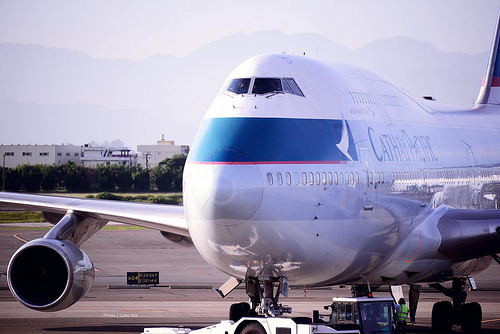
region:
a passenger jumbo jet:
[23, 31, 490, 323]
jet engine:
[6, 227, 97, 313]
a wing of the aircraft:
[5, 171, 190, 243]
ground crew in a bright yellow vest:
[388, 290, 412, 326]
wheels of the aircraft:
[426, 293, 481, 328]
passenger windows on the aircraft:
[265, 170, 456, 185]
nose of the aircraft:
[187, 152, 268, 222]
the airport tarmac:
[105, 236, 188, 317]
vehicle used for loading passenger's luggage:
[150, 295, 395, 330]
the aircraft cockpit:
[227, 74, 306, 106]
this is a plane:
[4, 46, 499, 277]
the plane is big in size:
[5, 28, 497, 285]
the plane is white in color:
[8, 44, 495, 271]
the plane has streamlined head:
[183, 154, 263, 226]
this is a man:
[393, 295, 410, 322]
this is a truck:
[254, 292, 392, 331]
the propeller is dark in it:
[16, 264, 58, 288]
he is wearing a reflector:
[393, 305, 404, 317]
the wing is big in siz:
[1, 195, 156, 310]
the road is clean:
[129, 299, 190, 315]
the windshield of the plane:
[224, 75, 305, 102]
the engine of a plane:
[3, 235, 96, 314]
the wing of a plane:
[1, 188, 193, 248]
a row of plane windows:
[263, 170, 362, 188]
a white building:
[0, 142, 84, 167]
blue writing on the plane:
[363, 125, 442, 165]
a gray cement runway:
[0, 220, 499, 332]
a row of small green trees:
[0, 152, 190, 199]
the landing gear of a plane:
[248, 272, 293, 316]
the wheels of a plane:
[431, 298, 487, 330]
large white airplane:
[32, 63, 477, 315]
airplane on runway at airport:
[20, 63, 488, 316]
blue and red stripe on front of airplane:
[178, 116, 388, 173]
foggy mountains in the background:
[15, 23, 464, 131]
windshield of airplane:
[209, 73, 304, 107]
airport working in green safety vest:
[387, 285, 419, 327]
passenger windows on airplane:
[269, 163, 494, 194]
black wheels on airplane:
[432, 295, 489, 327]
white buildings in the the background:
[10, 121, 195, 177]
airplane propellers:
[4, 231, 94, 315]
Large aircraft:
[141, 37, 439, 268]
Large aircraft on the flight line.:
[36, 47, 278, 325]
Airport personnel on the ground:
[383, 285, 423, 323]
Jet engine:
[5, 227, 128, 327]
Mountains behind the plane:
[119, 34, 379, 114]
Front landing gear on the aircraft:
[218, 282, 278, 329]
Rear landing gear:
[421, 281, 498, 330]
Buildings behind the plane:
[81, 135, 173, 172]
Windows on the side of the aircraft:
[260, 171, 438, 186]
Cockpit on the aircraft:
[234, 73, 315, 97]